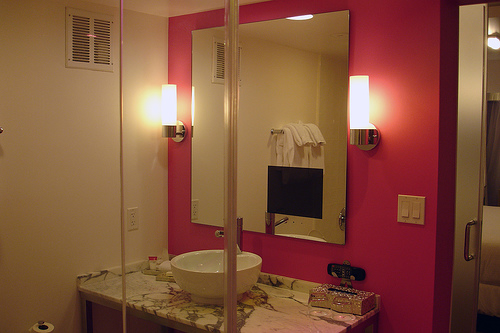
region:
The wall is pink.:
[366, 41, 427, 132]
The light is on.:
[322, 78, 402, 153]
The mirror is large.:
[159, 8, 381, 288]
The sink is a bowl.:
[149, 222, 299, 300]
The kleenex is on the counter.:
[302, 278, 379, 332]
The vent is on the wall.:
[53, 6, 123, 68]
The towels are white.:
[279, 112, 336, 182]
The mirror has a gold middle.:
[209, 9, 280, 330]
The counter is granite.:
[106, 256, 178, 317]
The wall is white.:
[35, 95, 115, 220]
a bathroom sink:
[89, 175, 337, 330]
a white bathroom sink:
[154, 210, 283, 330]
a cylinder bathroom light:
[321, 64, 385, 178]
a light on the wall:
[337, 77, 389, 157]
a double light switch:
[389, 182, 445, 251]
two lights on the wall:
[136, 61, 412, 195]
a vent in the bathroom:
[57, 5, 172, 130]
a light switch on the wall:
[103, 186, 167, 253]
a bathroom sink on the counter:
[135, 204, 361, 331]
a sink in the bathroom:
[154, 196, 304, 319]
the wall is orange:
[366, 68, 444, 168]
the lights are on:
[334, 81, 376, 129]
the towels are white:
[273, 126, 325, 165]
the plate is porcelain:
[163, 252, 259, 299]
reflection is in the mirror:
[259, 126, 338, 239]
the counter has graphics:
[133, 281, 168, 314]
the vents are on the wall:
[41, 53, 119, 72]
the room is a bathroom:
[4, 53, 492, 321]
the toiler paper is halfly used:
[26, 313, 66, 332]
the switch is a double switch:
[391, 188, 427, 233]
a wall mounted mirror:
[185, 7, 356, 251]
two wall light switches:
[391, 187, 428, 233]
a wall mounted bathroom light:
[150, 79, 190, 149]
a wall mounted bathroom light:
[342, 70, 379, 154]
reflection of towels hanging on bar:
[265, 117, 325, 170]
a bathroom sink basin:
[164, 212, 264, 307]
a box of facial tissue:
[300, 279, 377, 320]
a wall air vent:
[61, 5, 115, 72]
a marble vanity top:
[80, 252, 378, 332]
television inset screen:
[262, 162, 324, 222]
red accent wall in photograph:
[157, 18, 421, 318]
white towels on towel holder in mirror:
[258, 91, 335, 206]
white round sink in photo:
[141, 217, 242, 285]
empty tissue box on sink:
[294, 280, 386, 324]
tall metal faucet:
[212, 202, 250, 259]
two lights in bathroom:
[147, 70, 444, 164]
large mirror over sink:
[182, 28, 339, 253]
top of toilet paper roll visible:
[20, 305, 70, 329]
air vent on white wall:
[55, 11, 129, 81]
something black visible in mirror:
[248, 164, 330, 216]